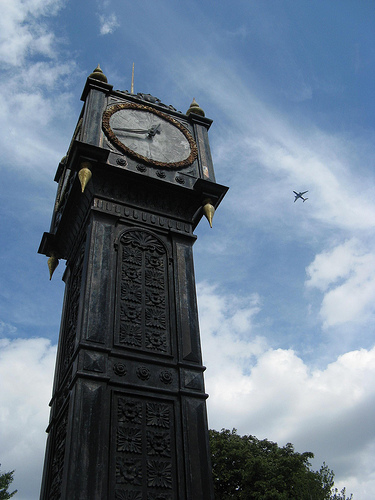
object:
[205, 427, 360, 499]
bushy tree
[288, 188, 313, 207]
airplane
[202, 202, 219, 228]
ornamental spike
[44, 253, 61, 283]
ornamental spike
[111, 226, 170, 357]
ornate designs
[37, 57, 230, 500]
tower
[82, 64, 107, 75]
ornamental spike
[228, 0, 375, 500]
air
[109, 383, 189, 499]
etched pattern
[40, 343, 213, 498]
stone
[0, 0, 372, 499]
sky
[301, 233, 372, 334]
white clouds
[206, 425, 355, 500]
bushy section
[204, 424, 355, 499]
leaves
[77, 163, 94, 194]
decorative spikes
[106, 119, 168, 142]
two hands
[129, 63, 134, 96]
antennae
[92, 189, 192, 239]
small section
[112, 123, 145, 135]
black hands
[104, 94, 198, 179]
face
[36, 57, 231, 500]
clock tower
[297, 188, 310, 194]
wing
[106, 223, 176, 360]
pattern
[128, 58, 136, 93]
pole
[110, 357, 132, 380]
rosette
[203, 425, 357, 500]
tree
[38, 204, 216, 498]
pillar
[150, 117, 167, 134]
hands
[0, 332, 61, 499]
cloud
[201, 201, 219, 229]
object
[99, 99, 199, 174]
clock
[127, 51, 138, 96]
lighting rod